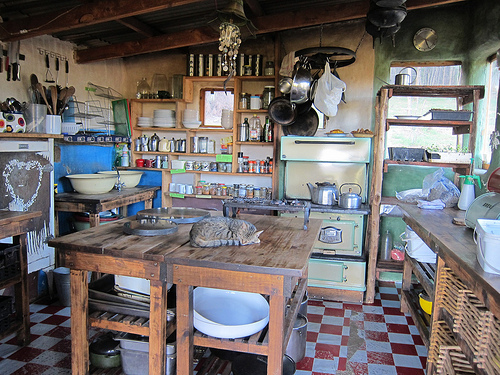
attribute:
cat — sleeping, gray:
[189, 220, 263, 251]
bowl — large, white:
[188, 286, 270, 341]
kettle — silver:
[305, 180, 339, 207]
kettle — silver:
[333, 184, 367, 211]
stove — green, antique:
[276, 134, 371, 294]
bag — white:
[312, 58, 347, 119]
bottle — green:
[453, 171, 482, 212]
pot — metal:
[287, 56, 317, 106]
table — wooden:
[46, 216, 326, 375]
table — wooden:
[0, 206, 45, 351]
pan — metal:
[418, 107, 473, 124]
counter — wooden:
[397, 210, 499, 374]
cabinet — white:
[0, 134, 56, 276]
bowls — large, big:
[59, 165, 147, 198]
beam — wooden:
[2, 0, 189, 41]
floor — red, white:
[0, 280, 427, 374]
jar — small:
[219, 186, 230, 198]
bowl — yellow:
[411, 289, 435, 317]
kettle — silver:
[390, 66, 420, 89]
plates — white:
[154, 105, 178, 130]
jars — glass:
[191, 176, 276, 204]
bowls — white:
[218, 107, 236, 132]